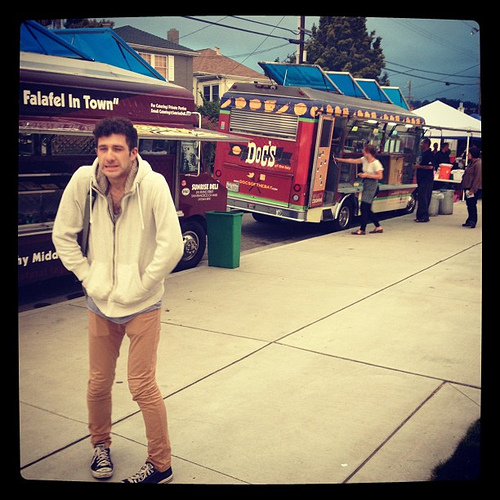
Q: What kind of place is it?
A: It is a sidewalk.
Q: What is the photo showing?
A: It is showing a sidewalk.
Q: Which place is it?
A: It is a sidewalk.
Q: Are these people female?
A: No, they are both male and female.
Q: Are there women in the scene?
A: Yes, there is a woman.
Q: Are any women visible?
A: Yes, there is a woman.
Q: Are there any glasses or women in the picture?
A: Yes, there is a woman.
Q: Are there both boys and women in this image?
A: No, there is a woman but no boys.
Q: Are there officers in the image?
A: No, there are no officers.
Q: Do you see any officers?
A: No, there are no officers.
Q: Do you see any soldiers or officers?
A: No, there are no officers or soldiers.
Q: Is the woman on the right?
A: Yes, the woman is on the right of the image.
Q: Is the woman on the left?
A: No, the woman is on the right of the image.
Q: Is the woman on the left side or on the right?
A: The woman is on the right of the image.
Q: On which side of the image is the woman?
A: The woman is on the right of the image.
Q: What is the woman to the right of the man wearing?
A: The woman is wearing pants.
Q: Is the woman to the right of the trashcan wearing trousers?
A: Yes, the woman is wearing trousers.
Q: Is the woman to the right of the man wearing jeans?
A: No, the woman is wearing trousers.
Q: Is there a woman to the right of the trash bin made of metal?
A: Yes, there is a woman to the right of the trash can.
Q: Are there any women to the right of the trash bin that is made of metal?
A: Yes, there is a woman to the right of the trash can.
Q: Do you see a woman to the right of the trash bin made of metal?
A: Yes, there is a woman to the right of the trash can.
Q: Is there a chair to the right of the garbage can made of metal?
A: No, there is a woman to the right of the garbage can.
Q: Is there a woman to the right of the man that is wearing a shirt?
A: Yes, there is a woman to the right of the man.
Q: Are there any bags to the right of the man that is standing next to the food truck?
A: No, there is a woman to the right of the man.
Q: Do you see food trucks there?
A: Yes, there is a food truck.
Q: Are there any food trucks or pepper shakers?
A: Yes, there is a food truck.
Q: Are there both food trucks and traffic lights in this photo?
A: No, there is a food truck but no traffic lights.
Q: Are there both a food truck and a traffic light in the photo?
A: No, there is a food truck but no traffic lights.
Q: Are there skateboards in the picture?
A: No, there are no skateboards.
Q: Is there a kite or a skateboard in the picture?
A: No, there are no skateboards or kites.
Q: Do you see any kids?
A: No, there are no kids.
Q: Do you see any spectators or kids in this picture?
A: No, there are no kids or spectators.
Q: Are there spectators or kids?
A: No, there are no kids or spectators.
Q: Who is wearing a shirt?
A: The man is wearing a shirt.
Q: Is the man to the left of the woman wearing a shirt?
A: Yes, the man is wearing a shirt.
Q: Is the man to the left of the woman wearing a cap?
A: No, the man is wearing a shirt.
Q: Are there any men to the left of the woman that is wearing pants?
A: Yes, there is a man to the left of the woman.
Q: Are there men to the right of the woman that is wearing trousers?
A: No, the man is to the left of the woman.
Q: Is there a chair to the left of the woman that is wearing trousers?
A: No, there is a man to the left of the woman.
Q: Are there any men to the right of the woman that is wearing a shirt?
A: Yes, there is a man to the right of the woman.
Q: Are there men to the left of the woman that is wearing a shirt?
A: No, the man is to the right of the woman.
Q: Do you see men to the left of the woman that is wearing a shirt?
A: No, the man is to the right of the woman.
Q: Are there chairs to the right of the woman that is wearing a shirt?
A: No, there is a man to the right of the woman.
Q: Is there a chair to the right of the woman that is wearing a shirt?
A: No, there is a man to the right of the woman.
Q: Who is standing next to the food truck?
A: The man is standing next to the food truck.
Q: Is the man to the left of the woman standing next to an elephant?
A: No, the man is standing next to the food truck.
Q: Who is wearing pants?
A: The man is wearing pants.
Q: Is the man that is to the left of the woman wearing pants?
A: Yes, the man is wearing pants.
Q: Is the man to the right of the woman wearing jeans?
A: No, the man is wearing pants.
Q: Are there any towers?
A: No, there are no towers.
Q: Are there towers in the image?
A: No, there are no towers.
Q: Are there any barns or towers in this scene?
A: No, there are no towers or barns.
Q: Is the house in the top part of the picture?
A: Yes, the house is in the top of the image.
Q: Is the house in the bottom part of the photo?
A: No, the house is in the top of the image.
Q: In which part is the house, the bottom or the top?
A: The house is in the top of the image.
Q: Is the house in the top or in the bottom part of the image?
A: The house is in the top of the image.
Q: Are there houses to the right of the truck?
A: Yes, there is a house to the right of the truck.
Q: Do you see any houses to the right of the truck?
A: Yes, there is a house to the right of the truck.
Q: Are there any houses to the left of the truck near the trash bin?
A: No, the house is to the right of the truck.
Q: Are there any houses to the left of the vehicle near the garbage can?
A: No, the house is to the right of the truck.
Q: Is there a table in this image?
A: Yes, there is a table.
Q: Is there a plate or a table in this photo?
A: Yes, there is a table.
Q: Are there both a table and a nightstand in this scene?
A: No, there is a table but no nightstands.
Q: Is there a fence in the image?
A: No, there are no fences.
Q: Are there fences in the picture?
A: No, there are no fences.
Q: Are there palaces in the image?
A: No, there are no palaces.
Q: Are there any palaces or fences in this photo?
A: No, there are no palaces or fences.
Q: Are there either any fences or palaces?
A: No, there are no palaces or fences.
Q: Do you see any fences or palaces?
A: No, there are no palaces or fences.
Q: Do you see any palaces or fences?
A: No, there are no palaces or fences.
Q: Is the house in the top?
A: Yes, the house is in the top of the image.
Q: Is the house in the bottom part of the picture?
A: No, the house is in the top of the image.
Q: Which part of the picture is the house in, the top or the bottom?
A: The house is in the top of the image.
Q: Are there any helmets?
A: No, there are no helmets.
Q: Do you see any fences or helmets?
A: No, there are no helmets or fences.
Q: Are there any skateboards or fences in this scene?
A: No, there are no fences or skateboards.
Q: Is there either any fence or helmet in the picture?
A: No, there are no helmets or fences.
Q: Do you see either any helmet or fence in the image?
A: No, there are no helmets or fences.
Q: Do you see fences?
A: No, there are no fences.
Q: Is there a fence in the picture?
A: No, there are no fences.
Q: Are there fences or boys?
A: No, there are no fences or boys.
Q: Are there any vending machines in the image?
A: No, there are no vending machines.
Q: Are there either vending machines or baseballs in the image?
A: No, there are no vending machines or baseballs.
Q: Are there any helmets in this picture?
A: No, there are no helmets.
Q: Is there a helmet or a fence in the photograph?
A: No, there are no helmets or fences.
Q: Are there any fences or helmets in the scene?
A: No, there are no helmets or fences.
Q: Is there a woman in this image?
A: Yes, there is a woman.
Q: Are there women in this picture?
A: Yes, there is a woman.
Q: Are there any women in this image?
A: Yes, there is a woman.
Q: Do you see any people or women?
A: Yes, there is a woman.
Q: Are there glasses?
A: No, there are no glasses.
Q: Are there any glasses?
A: No, there are no glasses.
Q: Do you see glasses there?
A: No, there are no glasses.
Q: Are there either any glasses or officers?
A: No, there are no glasses or officers.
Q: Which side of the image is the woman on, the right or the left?
A: The woman is on the right of the image.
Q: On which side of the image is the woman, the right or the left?
A: The woman is on the right of the image.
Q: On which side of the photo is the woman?
A: The woman is on the right of the image.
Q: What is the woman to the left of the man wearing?
A: The woman is wearing a shirt.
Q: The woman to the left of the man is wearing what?
A: The woman is wearing a shirt.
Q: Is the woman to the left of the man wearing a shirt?
A: Yes, the woman is wearing a shirt.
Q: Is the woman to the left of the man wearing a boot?
A: No, the woman is wearing a shirt.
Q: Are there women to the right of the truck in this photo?
A: Yes, there is a woman to the right of the truck.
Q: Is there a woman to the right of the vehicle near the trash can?
A: Yes, there is a woman to the right of the truck.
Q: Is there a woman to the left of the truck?
A: No, the woman is to the right of the truck.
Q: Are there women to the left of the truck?
A: No, the woman is to the right of the truck.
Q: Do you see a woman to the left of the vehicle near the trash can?
A: No, the woman is to the right of the truck.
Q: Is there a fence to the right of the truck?
A: No, there is a woman to the right of the truck.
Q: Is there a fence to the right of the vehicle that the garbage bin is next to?
A: No, there is a woman to the right of the truck.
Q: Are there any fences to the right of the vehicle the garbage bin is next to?
A: No, there is a woman to the right of the truck.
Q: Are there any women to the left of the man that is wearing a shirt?
A: Yes, there is a woman to the left of the man.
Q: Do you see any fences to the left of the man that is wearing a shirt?
A: No, there is a woman to the left of the man.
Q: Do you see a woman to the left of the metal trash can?
A: Yes, there is a woman to the left of the garbage bin.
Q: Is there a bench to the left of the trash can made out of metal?
A: No, there is a woman to the left of the garbage bin.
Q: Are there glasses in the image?
A: No, there are no glasses.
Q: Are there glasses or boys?
A: No, there are no glasses or boys.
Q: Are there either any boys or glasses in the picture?
A: No, there are no glasses or boys.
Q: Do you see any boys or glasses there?
A: No, there are no glasses or boys.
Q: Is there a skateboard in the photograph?
A: No, there are no skateboards.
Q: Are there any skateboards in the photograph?
A: No, there are no skateboards.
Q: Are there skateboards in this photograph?
A: No, there are no skateboards.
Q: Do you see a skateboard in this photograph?
A: No, there are no skateboards.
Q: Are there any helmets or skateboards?
A: No, there are no skateboards or helmets.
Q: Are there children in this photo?
A: No, there are no children.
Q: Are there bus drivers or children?
A: No, there are no children or bus drivers.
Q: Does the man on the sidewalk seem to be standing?
A: Yes, the man is standing.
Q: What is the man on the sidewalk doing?
A: The man is standing.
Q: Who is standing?
A: The man is standing.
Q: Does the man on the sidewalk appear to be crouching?
A: No, the man is standing.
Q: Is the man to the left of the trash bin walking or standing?
A: The man is standing.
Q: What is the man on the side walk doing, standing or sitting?
A: The man is standing.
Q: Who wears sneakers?
A: The man wears sneakers.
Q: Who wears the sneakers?
A: The man wears sneakers.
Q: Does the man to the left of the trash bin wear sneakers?
A: Yes, the man wears sneakers.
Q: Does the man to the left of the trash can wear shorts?
A: No, the man wears sneakers.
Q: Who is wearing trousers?
A: The man is wearing trousers.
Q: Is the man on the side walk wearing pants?
A: Yes, the man is wearing pants.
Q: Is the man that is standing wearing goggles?
A: No, the man is wearing pants.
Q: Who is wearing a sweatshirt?
A: The man is wearing a sweatshirt.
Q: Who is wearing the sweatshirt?
A: The man is wearing a sweatshirt.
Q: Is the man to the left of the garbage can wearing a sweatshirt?
A: Yes, the man is wearing a sweatshirt.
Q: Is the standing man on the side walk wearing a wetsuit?
A: No, the man is wearing a sweatshirt.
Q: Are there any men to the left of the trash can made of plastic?
A: Yes, there is a man to the left of the trash can.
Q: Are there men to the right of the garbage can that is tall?
A: No, the man is to the left of the trashcan.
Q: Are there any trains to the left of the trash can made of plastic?
A: No, there is a man to the left of the trashcan.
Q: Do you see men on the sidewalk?
A: Yes, there is a man on the sidewalk.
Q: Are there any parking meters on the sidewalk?
A: No, there is a man on the sidewalk.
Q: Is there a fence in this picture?
A: No, there are no fences.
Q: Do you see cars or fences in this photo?
A: No, there are no fences or cars.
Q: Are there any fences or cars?
A: No, there are no fences or cars.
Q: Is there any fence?
A: No, there are no fences.